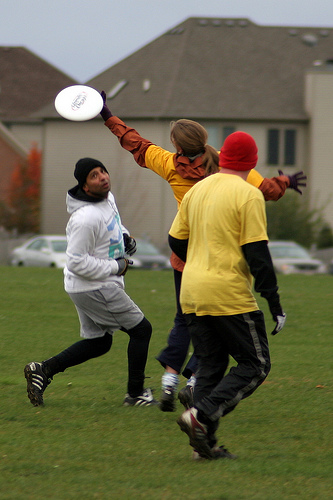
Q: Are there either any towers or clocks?
A: No, there are no towers or clocks.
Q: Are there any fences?
A: No, there are no fences.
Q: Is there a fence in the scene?
A: No, there are no fences.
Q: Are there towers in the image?
A: No, there are no towers.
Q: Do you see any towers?
A: No, there are no towers.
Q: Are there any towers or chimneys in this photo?
A: No, there are no towers or chimneys.